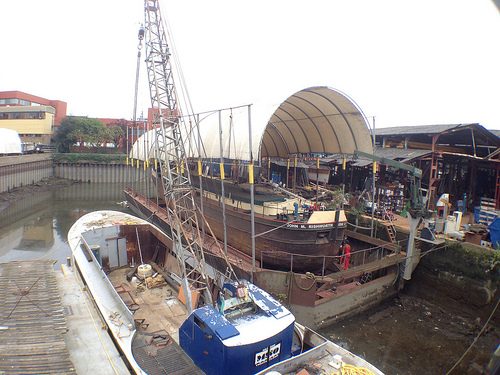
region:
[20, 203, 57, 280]
reflection of yellow building in water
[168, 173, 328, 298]
brown boat resembles ark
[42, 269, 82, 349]
brown aged wooden pier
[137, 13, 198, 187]
metal part of crane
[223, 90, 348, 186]
arched canopy over boat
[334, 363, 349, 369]
yellow rope on boat deck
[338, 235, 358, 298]
person wearing red outfit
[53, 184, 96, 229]
calm body of water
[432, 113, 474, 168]
corrugated metal roof on shelter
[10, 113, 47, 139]
yellow building in distance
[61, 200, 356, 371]
white boat with a blue cab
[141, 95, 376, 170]
large white dome like tent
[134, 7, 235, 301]
metal crane attached to a boat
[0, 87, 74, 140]
red and beige buildings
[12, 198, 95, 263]
dirty water below the boat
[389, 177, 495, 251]
dock full of various items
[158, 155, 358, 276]
large rusted brown boat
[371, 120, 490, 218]
tent over a dock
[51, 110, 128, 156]
small group of trees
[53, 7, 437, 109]
white sky with no clouds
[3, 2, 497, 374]
boats on a body of water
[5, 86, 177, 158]
red and yellow building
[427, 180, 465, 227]
person inside an warehouse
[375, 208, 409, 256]
a ladder on side a boat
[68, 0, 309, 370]
a crane on a boat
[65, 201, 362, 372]
a white boat with a crane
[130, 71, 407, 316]
a boat over a container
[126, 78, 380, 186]
roof of boat is white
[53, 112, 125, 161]
gree trees in front of building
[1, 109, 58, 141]
part yellow of a building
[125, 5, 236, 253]
Tower lift on back of boat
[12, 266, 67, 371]
The pier is made of wood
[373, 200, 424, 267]
a ladder is going down to the water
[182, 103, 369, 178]
A tent over the top of boat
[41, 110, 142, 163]
group of trees in the background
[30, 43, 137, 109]
The sky is very cloudy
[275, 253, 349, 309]
rope attached to the boat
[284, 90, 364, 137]
Metal bracing on the tent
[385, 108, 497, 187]
Building in the background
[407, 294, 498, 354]
rocks inside the water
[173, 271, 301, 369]
blue part of crane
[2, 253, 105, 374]
pier beside blue and white boat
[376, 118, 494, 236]
shelter in background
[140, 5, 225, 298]
crane on blue and white boat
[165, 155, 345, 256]
brown and white boat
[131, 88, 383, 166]
white canopy over shelter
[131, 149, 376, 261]
metal rods holding up shelter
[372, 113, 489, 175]
roof over background shelter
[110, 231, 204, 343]
inside of blue and white boat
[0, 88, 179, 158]
brick buildings in background